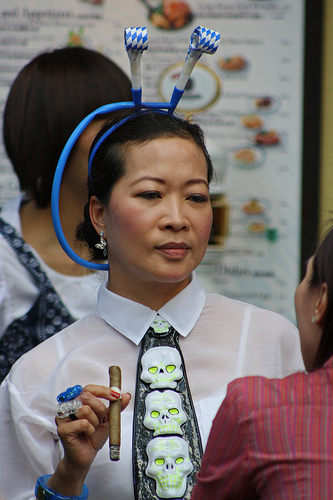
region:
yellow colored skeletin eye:
[145, 365, 156, 373]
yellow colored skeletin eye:
[165, 363, 171, 370]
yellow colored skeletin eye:
[149, 407, 155, 414]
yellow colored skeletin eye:
[150, 454, 161, 463]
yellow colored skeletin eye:
[173, 455, 179, 460]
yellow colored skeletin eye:
[152, 319, 157, 324]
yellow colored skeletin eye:
[160, 318, 165, 321]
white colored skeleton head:
[138, 342, 180, 388]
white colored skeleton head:
[141, 389, 188, 434]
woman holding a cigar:
[97, 360, 134, 465]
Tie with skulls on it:
[128, 334, 213, 499]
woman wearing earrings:
[91, 224, 113, 251]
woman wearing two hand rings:
[49, 378, 103, 428]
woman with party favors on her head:
[51, 20, 240, 158]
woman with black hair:
[90, 115, 240, 264]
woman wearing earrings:
[84, 227, 119, 267]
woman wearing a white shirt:
[199, 307, 266, 376]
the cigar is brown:
[84, 403, 128, 476]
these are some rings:
[60, 384, 84, 430]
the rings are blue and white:
[48, 365, 100, 447]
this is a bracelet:
[20, 485, 69, 494]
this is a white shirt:
[50, 358, 62, 367]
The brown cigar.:
[103, 362, 126, 469]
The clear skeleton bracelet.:
[56, 402, 87, 421]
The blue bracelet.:
[31, 471, 93, 499]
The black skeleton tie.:
[136, 312, 201, 499]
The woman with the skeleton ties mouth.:
[155, 238, 191, 262]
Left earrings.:
[94, 229, 107, 255]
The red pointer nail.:
[109, 389, 122, 403]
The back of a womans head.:
[284, 225, 330, 372]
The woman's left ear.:
[313, 282, 328, 337]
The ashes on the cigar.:
[107, 443, 118, 467]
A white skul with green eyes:
[147, 439, 198, 494]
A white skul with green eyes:
[145, 387, 187, 435]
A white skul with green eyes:
[137, 343, 184, 386]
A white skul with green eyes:
[151, 311, 172, 335]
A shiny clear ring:
[52, 401, 83, 418]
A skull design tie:
[139, 322, 200, 478]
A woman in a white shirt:
[41, 146, 257, 398]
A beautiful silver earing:
[95, 222, 109, 256]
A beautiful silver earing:
[305, 310, 323, 322]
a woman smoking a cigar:
[64, 94, 273, 273]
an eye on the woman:
[129, 178, 167, 208]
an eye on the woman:
[188, 186, 215, 214]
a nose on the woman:
[163, 184, 182, 214]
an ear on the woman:
[93, 190, 142, 261]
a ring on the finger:
[50, 382, 85, 408]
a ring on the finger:
[55, 399, 84, 418]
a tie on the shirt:
[119, 302, 232, 486]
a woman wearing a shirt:
[246, 307, 326, 437]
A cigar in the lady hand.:
[92, 362, 130, 468]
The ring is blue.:
[52, 384, 91, 398]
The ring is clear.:
[55, 403, 93, 415]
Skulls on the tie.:
[142, 343, 183, 435]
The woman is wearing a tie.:
[133, 318, 205, 481]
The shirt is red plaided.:
[232, 381, 324, 484]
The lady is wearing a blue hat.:
[96, 32, 219, 131]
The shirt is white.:
[54, 302, 286, 401]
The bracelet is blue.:
[31, 480, 94, 499]